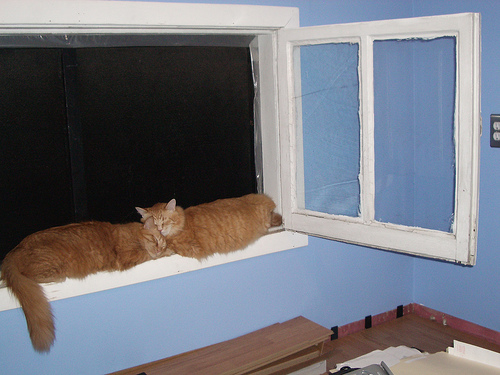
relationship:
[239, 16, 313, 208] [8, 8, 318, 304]
frame around window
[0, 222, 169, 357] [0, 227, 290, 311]
cat on window sill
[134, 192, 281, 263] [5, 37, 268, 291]
cat in window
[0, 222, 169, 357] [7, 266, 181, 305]
cat sleeping in window sill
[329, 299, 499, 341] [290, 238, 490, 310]
red strip at bottom of wall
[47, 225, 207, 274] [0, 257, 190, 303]
cat on window sill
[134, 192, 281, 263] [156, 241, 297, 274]
cat on window sill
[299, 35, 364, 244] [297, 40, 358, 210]
window in pane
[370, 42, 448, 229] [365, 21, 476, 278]
glass in pane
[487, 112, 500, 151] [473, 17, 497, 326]
outlet on wall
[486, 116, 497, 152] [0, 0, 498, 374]
outlet on wall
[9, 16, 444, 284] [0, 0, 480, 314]
window with frame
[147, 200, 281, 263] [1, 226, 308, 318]
cat sleeping on sill